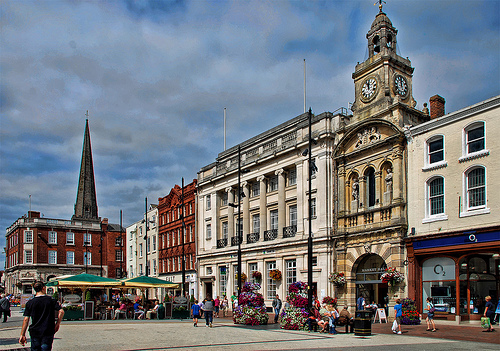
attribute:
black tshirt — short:
[19, 279, 69, 330]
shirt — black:
[31, 295, 55, 330]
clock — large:
[355, 72, 385, 104]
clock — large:
[390, 73, 410, 98]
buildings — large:
[152, 137, 459, 313]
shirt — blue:
[389, 299, 404, 314]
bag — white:
[388, 317, 400, 334]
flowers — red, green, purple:
[230, 276, 267, 322]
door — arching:
[349, 254, 389, 321]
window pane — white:
[419, 209, 447, 222]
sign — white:
[365, 300, 400, 335]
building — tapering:
[4, 105, 132, 298]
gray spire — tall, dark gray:
[66, 101, 108, 241]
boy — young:
[190, 300, 200, 325]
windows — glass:
[218, 196, 303, 246]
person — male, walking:
[18, 280, 65, 349]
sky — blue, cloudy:
[3, 3, 216, 162]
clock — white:
[359, 72, 381, 102]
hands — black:
[365, 78, 371, 89]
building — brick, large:
[158, 177, 195, 298]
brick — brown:
[380, 243, 400, 260]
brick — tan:
[377, 234, 391, 258]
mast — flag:
[217, 102, 233, 149]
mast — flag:
[298, 55, 311, 109]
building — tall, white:
[198, 109, 351, 310]